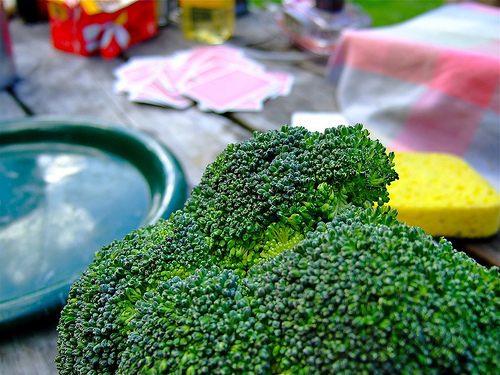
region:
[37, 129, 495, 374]
raw broccoli floret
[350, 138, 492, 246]
bright yellow sponge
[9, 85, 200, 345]
dark green plastic plate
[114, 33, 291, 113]
deck of cards sprawled out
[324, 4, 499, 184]
pink and blue checkered cloth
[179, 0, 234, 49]
bottle of yellow liquid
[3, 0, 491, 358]
numerous items on a picnic table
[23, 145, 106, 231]
sun light reflecting on a plate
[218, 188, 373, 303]
dark and light green florets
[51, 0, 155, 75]
red and white box on a table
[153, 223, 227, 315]
the broccoli is green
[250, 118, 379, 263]
the broccoli is green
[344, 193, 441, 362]
the broccoli is green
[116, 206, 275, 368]
the broccoli is green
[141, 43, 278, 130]
the cards on the table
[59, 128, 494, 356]
green heads of broccoli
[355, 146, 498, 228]
yellow sponge on table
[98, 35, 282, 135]
playing cards on table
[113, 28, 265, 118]
red and white playing cards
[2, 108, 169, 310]
green plate on table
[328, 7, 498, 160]
gray and red tablecloth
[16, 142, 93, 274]
reflection on green plate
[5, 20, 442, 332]
wood slats of picnic table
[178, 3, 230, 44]
bottle on back of table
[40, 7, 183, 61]
red and white container on table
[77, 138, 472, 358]
green broccoli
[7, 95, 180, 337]
round green plate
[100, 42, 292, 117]
deck of playing cards on table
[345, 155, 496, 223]
yellow sponge behind broccoli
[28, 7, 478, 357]
broccoli in focus and the rest of photo out of focus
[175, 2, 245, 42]
bottle with a yellow liquid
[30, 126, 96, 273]
reflection of light on plate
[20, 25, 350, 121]
large wooden table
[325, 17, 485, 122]
pink and white towel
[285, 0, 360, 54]
clear bottle with a black cap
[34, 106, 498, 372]
head of broccoli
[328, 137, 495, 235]
yellow sponge beside broccoli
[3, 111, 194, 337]
green plate beside broccoli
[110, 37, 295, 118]
deck of card spread out on a wooden table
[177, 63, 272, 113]
card in a pile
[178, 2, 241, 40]
bottle of yellowish tint liquid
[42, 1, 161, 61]
red yellow and white box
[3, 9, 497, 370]
wooden table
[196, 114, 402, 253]
broccoli spear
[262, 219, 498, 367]
broccoli spear